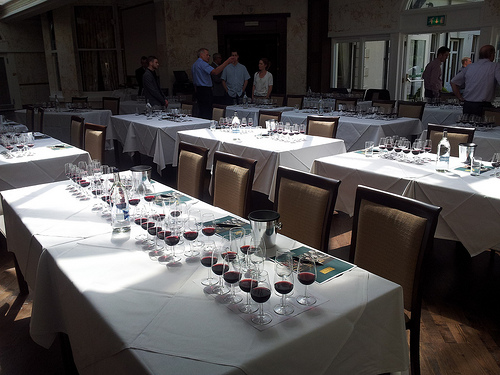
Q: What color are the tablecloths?
A: White.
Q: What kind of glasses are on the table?
A: Wine glasses.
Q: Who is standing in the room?
A: Men and women.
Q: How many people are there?
A: Nine.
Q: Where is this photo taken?
A: Inside of a banquet room.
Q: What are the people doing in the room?
A: Talking to each other.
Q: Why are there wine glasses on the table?
A: They are there for people to drink the wine.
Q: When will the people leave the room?
A: When they have finished talking to each other.